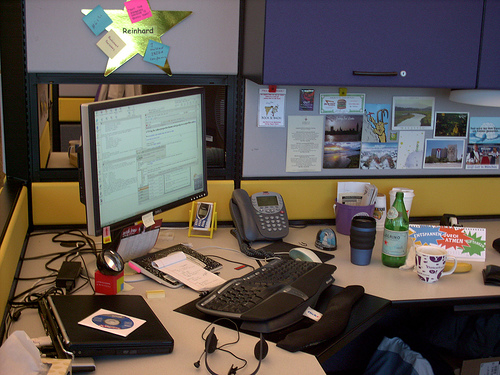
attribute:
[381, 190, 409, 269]
bottle — green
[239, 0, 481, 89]
cabinet — purple, blue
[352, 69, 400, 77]
handle — black, narrow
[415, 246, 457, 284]
cup — white, black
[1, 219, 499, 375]
desk — tan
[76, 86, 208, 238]
monitor — on, computer, desktop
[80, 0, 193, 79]
star — golden, shiny, gold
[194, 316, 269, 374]
headpiece — black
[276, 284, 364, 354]
armrest — black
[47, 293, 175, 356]
laptop — closed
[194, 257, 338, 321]
keyboard — black, ergonomic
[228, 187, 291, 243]
telephone — gray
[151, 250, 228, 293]
notebook — small, folded down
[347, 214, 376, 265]
coffee mug — blue, black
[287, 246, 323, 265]
computer mouse — white, green